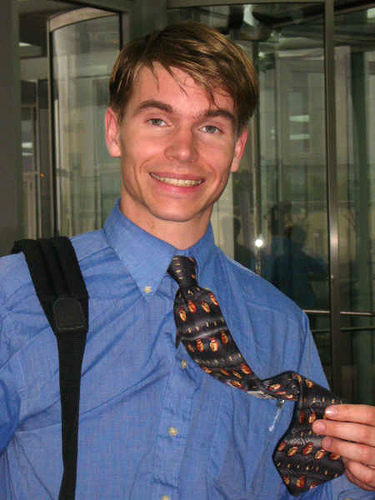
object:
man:
[0, 23, 375, 500]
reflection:
[270, 223, 331, 334]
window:
[333, 14, 375, 411]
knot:
[167, 255, 201, 286]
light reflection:
[251, 232, 263, 251]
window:
[217, 0, 332, 382]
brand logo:
[248, 389, 271, 401]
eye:
[142, 115, 171, 131]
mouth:
[147, 169, 207, 200]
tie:
[167, 255, 346, 495]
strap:
[10, 233, 89, 500]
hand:
[312, 402, 375, 492]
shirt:
[0, 198, 375, 500]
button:
[143, 285, 151, 297]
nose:
[164, 126, 199, 164]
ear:
[104, 107, 123, 158]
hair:
[107, 22, 258, 140]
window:
[282, 33, 327, 238]